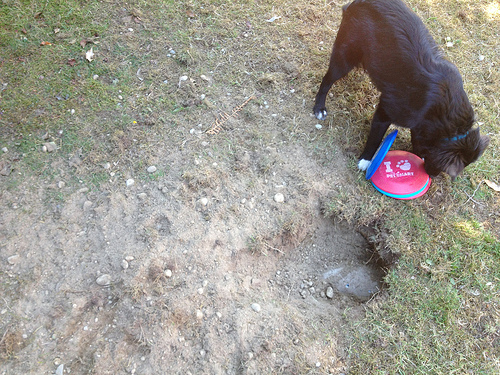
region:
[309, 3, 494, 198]
this is a dog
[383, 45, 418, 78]
the dog is black in color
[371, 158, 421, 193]
these are playing kits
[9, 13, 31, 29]
this is a grass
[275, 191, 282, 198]
this is a stone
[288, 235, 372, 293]
this is a whole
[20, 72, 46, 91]
the grass are green in color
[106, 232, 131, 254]
this is the soil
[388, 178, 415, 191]
the kit is red in color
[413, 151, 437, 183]
the dog is biting the kit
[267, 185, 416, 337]
hole in the ground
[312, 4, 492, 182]
a dog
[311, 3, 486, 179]
a black dog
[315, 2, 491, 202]
a dog plays with frisbees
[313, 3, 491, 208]
a dog with a stack of frisbees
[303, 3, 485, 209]
a dog with no leach on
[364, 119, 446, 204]
the frisbees are blue and red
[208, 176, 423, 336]
a hole dug in the dirt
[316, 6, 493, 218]
a dog with it's nose to the ground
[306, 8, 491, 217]
the dog wears a collar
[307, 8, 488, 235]
the dog has white feet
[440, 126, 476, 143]
blue dog collar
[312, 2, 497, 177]
Black dog on grass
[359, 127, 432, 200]
Pile of stacked Frisbees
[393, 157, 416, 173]
White paw print on Frisbee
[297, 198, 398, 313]
hole dug in ground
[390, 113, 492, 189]
Dog smelling Frisbee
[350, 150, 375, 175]
White dog paw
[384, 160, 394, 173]
Letter I on a frisbee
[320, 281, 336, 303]
Gray rock in a hole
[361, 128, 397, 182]
Blue Frisbee standing sideways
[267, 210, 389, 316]
this is a hole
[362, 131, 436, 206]
these are cone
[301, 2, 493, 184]
this is a dog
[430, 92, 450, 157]
the dog's fur is black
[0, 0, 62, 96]
the is a grass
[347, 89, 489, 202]
the dog is sniffing something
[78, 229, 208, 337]
this is soil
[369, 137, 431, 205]
the cone is blue, red and green in color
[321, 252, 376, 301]
there is an object in the ground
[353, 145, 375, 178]
the dog's leg is white